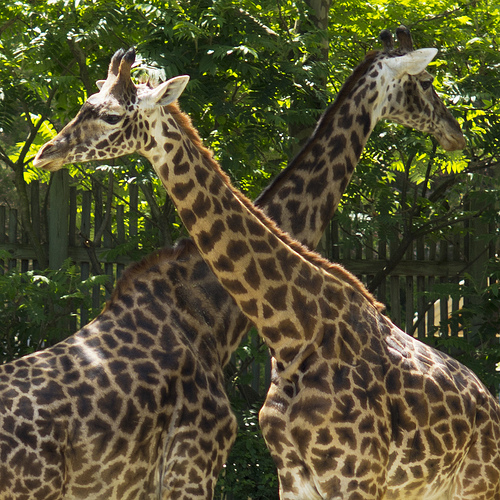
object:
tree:
[0, 0, 105, 300]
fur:
[169, 103, 388, 320]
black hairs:
[112, 43, 148, 62]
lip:
[28, 159, 47, 170]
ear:
[149, 81, 196, 121]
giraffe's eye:
[100, 109, 127, 126]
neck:
[324, 109, 355, 212]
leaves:
[11, 17, 41, 59]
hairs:
[333, 265, 375, 296]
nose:
[31, 140, 63, 158]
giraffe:
[16, 35, 498, 497]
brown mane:
[131, 66, 388, 314]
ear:
[383, 46, 439, 76]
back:
[390, 52, 433, 72]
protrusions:
[380, 25, 412, 55]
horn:
[98, 33, 120, 78]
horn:
[112, 44, 140, 91]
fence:
[377, 190, 499, 336]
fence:
[223, 326, 270, 404]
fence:
[2, 168, 106, 285]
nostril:
[54, 135, 72, 153]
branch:
[368, 231, 421, 288]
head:
[27, 35, 198, 181]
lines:
[326, 350, 389, 415]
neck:
[147, 105, 377, 346]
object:
[404, 257, 470, 346]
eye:
[94, 102, 127, 138]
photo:
[69, 49, 146, 167]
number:
[48, 185, 415, 389]